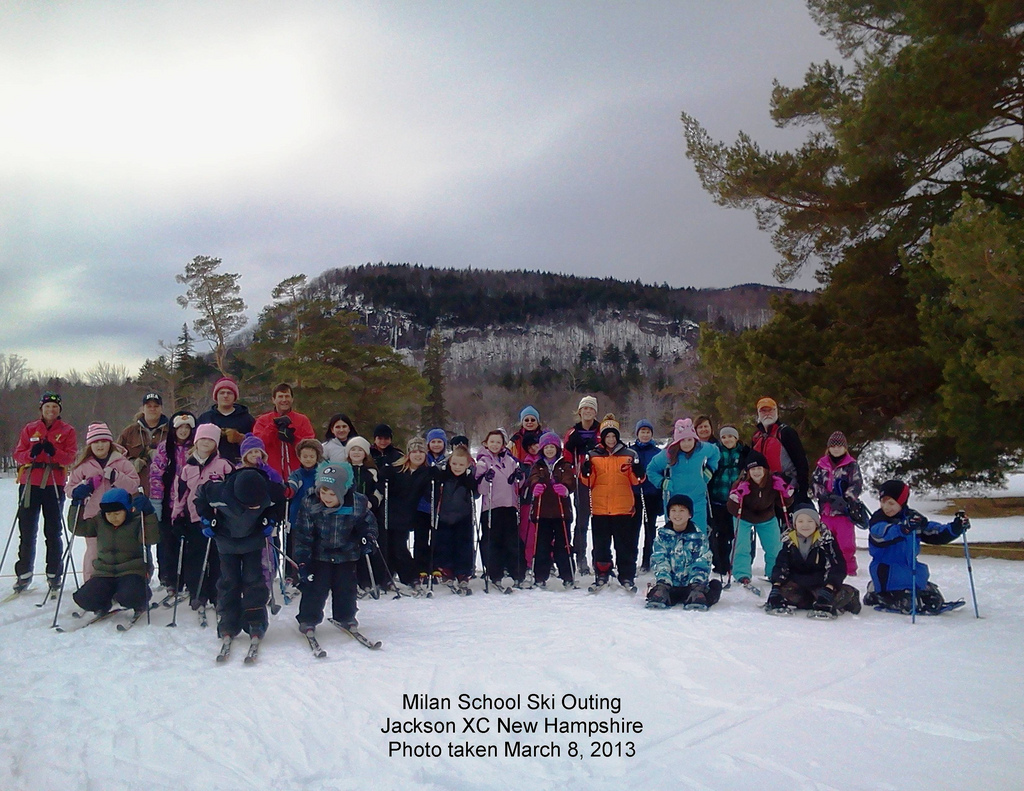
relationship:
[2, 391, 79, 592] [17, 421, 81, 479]
man in a jacket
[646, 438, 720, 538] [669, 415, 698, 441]
snow suit with hat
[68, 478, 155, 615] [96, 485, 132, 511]
boy wears hat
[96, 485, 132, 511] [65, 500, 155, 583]
hat wears jacket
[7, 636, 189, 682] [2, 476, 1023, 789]
ski track in snow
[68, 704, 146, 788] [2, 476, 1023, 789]
ski track in snow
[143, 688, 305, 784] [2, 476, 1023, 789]
ski track in snow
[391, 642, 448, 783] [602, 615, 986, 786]
ski track in ski track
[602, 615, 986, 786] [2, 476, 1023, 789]
ski track in snow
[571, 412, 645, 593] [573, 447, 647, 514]
person in coat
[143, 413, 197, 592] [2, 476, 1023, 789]
person standing in snow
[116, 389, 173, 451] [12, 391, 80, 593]
person standing in man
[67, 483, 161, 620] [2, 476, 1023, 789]
boy standing in snow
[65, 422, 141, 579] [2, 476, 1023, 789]
person standing in snow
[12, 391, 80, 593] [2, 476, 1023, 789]
man standing in snow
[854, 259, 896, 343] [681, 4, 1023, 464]
green leaves on tree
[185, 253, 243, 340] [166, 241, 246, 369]
green leaves on tree